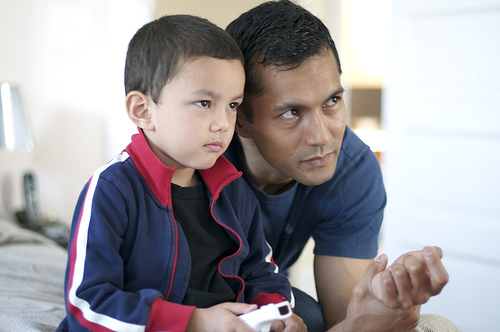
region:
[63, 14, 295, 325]
a brunette young child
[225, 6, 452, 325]
a black haired man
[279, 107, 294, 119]
the brown eye of a man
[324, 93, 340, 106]
the brown eye of a man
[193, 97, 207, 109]
the brown eye of a boy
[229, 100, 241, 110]
the brown eye of a boy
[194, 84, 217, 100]
the brown eyebrow of a boy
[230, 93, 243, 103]
the brown eyebrow of a boy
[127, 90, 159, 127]
the ear of a boy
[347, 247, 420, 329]
the hand of the man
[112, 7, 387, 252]
man and his son playing wii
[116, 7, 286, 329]
little boy playing wii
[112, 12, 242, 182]
little boy staring at the TV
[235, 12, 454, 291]
man staring at TV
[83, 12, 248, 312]
little boy in a blue and red sweatshirt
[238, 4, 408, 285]
man in a blue t-shirt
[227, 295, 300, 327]
white wii control in hand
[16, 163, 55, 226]
landline phone in its handset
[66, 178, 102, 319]
red and white stripe on blue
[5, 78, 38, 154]
lampshade next to the bed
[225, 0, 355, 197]
The man has hair.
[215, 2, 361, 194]
The hair is dark.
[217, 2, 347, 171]
Man's hair is groomed.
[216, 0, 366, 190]
Man's hair is short.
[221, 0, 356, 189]
Man's hair is black.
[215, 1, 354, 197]
Man's hair is neat.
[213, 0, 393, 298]
The man is wearing a shirt.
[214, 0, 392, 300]
The man's shirt is blue.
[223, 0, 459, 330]
The man is holding his wrist.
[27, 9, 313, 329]
The little boy is sitting.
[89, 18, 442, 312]
man and boy wearing blue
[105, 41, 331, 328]
boy holding white remote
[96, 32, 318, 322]
boy wearing a blue jacket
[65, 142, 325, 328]
blue jacket with red trim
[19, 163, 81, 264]
telephone on table behind boy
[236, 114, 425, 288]
man wearing a blue shirt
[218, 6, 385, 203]
man with dark brown hair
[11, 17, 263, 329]
boy sitting on a bed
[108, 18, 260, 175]
the boy is frowning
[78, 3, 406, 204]
the man and the boy are staring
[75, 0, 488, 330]
a man and child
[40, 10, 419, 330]
a man and child's head together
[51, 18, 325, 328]
a child wearing a jacket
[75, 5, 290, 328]
a young child playing the wii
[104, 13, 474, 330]
a child and man looking forward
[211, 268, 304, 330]
a white wii remote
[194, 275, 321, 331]
a white wii remote being held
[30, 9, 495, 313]
a child and man sitting down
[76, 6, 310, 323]
a child sitting down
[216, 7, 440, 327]
a man sitting down